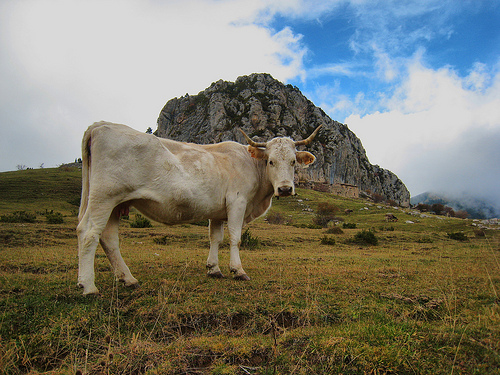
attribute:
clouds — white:
[386, 18, 459, 133]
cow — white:
[59, 117, 309, 302]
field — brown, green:
[8, 75, 492, 374]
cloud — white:
[353, 60, 498, 195]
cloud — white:
[307, 2, 481, 84]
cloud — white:
[2, 2, 343, 172]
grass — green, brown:
[318, 256, 415, 319]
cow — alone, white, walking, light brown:
[78, 117, 323, 293]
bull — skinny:
[72, 116, 305, 292]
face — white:
[258, 136, 310, 200]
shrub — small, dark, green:
[346, 227, 378, 247]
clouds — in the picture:
[400, 61, 492, 117]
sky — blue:
[324, 28, 379, 68]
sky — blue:
[389, 32, 461, 76]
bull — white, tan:
[73, 118, 334, 298]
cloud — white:
[344, 59, 498, 215]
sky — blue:
[0, 0, 499, 196]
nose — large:
[273, 172, 300, 208]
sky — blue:
[7, 5, 492, 216]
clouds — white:
[0, 3, 67, 160]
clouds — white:
[54, 1, 156, 149]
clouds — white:
[127, 3, 276, 82]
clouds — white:
[265, 7, 397, 144]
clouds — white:
[362, 7, 496, 208]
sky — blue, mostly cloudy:
[0, 15, 500, 225]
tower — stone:
[185, 52, 272, 123]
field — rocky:
[10, 197, 493, 372]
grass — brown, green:
[2, 217, 494, 369]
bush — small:
[25, 167, 36, 171]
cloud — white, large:
[2, 4, 312, 169]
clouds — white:
[144, 14, 427, 64]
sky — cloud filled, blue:
[335, 51, 487, 158]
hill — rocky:
[152, 47, 366, 145]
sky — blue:
[392, 8, 496, 97]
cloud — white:
[361, 42, 475, 164]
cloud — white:
[337, 60, 497, 168]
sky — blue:
[341, 4, 495, 90]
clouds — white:
[2, 0, 342, 172]